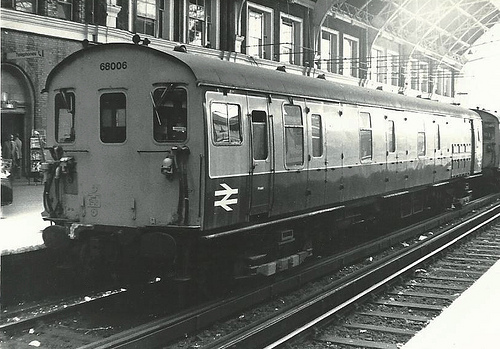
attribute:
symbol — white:
[211, 182, 255, 212]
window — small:
[142, 77, 198, 156]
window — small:
[351, 110, 383, 161]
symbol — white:
[215, 182, 237, 213]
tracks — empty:
[226, 202, 498, 345]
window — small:
[42, 79, 77, 144]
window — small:
[247, 109, 272, 159]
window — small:
[282, 101, 304, 125]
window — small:
[387, 119, 397, 152]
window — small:
[415, 129, 426, 159]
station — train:
[4, 10, 323, 299]